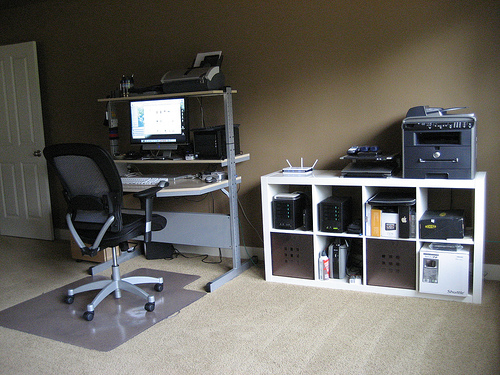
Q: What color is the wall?
A: Brown.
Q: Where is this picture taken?
A: Home office.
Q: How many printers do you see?
A: Two.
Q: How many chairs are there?
A: One.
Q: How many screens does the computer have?
A: One.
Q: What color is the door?
A: White.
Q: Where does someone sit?
A: The chair.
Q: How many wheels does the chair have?
A: Five.